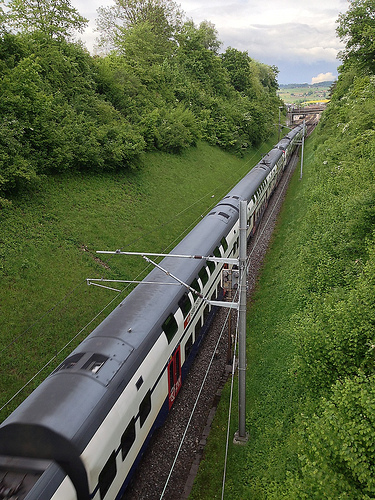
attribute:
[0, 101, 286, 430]
hill — leafy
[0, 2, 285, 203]
trees — green